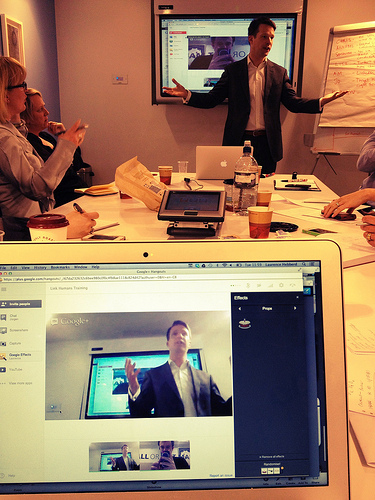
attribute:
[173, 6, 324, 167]
man — standing, white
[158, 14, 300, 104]
screen — on, white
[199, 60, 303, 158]
suit — black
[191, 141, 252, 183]
laptop — white, silver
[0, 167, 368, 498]
table — long, white